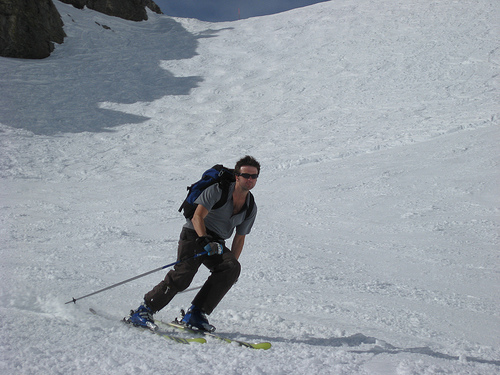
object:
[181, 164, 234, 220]
back pack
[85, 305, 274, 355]
snow ski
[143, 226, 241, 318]
pants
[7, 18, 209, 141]
shadows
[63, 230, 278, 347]
skiing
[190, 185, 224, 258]
arms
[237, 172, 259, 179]
goggles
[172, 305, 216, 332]
shoes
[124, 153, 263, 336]
man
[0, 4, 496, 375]
snow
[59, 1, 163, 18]
trees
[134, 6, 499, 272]
hill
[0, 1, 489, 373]
slope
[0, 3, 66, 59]
pine trees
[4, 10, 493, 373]
tracts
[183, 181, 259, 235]
shirt